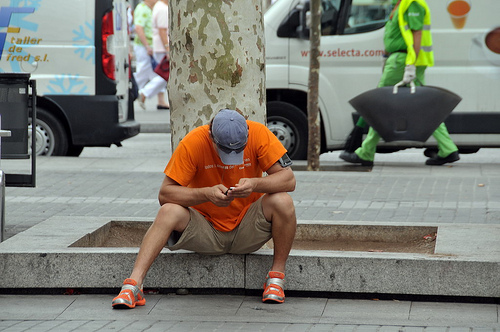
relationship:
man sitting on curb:
[111, 108, 297, 309] [0, 215, 499, 304]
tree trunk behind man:
[166, 0, 268, 177] [111, 108, 297, 309]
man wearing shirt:
[111, 108, 297, 309] [163, 120, 288, 232]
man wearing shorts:
[111, 108, 297, 309] [163, 192, 272, 256]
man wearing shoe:
[111, 108, 297, 309] [111, 277, 146, 309]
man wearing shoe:
[111, 108, 297, 309] [262, 268, 286, 303]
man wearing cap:
[111, 108, 297, 309] [211, 109, 247, 165]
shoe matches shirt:
[111, 277, 146, 309] [163, 120, 288, 232]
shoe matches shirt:
[262, 268, 286, 303] [163, 120, 288, 232]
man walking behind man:
[339, 0, 460, 166] [111, 108, 297, 309]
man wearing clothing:
[339, 0, 460, 166] [353, 0, 458, 161]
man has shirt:
[111, 108, 297, 309] [163, 120, 288, 232]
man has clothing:
[339, 0, 460, 166] [353, 0, 458, 161]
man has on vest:
[339, 0, 460, 166] [398, 0, 434, 67]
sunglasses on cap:
[211, 135, 247, 155] [211, 109, 247, 165]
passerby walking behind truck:
[136, 0, 168, 111] [0, 0, 140, 157]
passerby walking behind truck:
[132, 0, 168, 109] [0, 0, 140, 157]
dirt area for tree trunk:
[102, 226, 436, 254] [166, 0, 268, 177]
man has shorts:
[111, 108, 297, 309] [163, 192, 272, 256]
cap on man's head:
[211, 109, 247, 165] [207, 108, 250, 158]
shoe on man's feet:
[111, 277, 146, 309] [111, 275, 146, 308]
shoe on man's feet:
[262, 268, 286, 303] [262, 263, 288, 304]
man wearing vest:
[339, 0, 460, 166] [398, 0, 434, 67]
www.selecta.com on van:
[300, 49, 384, 59] [263, 0, 499, 160]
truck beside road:
[0, 0, 140, 157] [77, 132, 500, 162]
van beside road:
[263, 0, 499, 160] [77, 132, 500, 162]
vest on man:
[398, 0, 434, 67] [339, 0, 460, 166]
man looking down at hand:
[111, 108, 297, 309] [203, 183, 234, 207]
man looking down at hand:
[111, 108, 297, 309] [226, 177, 259, 197]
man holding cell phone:
[111, 108, 297, 309] [224, 187, 236, 195]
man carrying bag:
[339, 0, 460, 166] [348, 77, 463, 144]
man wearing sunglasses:
[111, 108, 297, 309] [211, 135, 247, 155]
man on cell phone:
[111, 108, 297, 309] [224, 187, 236, 195]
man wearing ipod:
[111, 108, 297, 309] [279, 152, 292, 167]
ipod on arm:
[279, 152, 292, 167] [226, 124, 296, 197]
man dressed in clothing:
[339, 0, 460, 166] [353, 0, 458, 161]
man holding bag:
[339, 0, 460, 166] [348, 77, 463, 144]